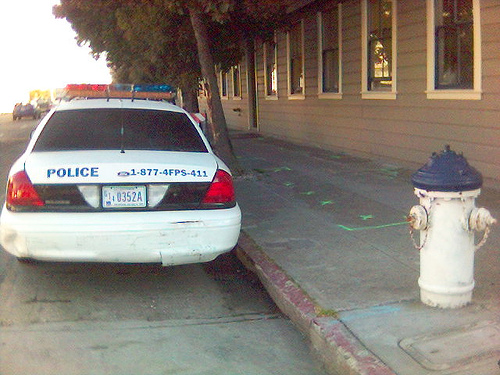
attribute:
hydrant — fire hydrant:
[405, 142, 497, 312]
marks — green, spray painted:
[277, 173, 298, 190]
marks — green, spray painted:
[299, 184, 316, 199]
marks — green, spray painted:
[315, 195, 338, 212]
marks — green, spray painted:
[356, 208, 376, 224]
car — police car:
[3, 69, 265, 285]